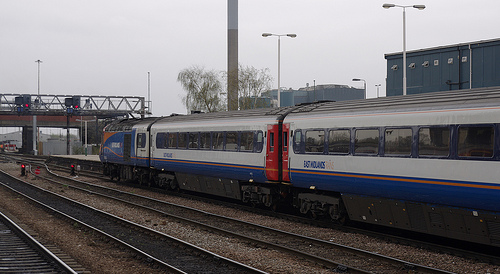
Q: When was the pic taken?
A: During day.